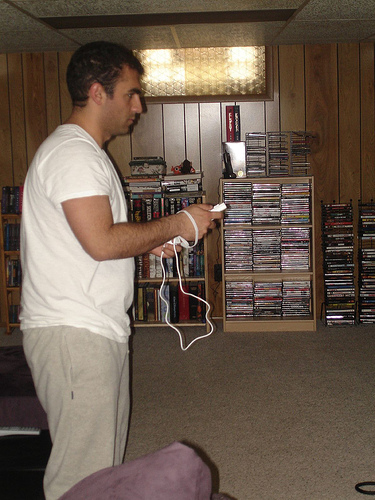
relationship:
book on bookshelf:
[133, 200, 142, 223] [131, 191, 219, 324]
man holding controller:
[18, 40, 228, 498] [165, 201, 227, 244]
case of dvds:
[219, 177, 326, 333] [319, 195, 373, 324]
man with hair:
[18, 40, 228, 498] [63, 35, 144, 109]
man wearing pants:
[18, 40, 228, 498] [28, 325, 141, 499]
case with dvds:
[214, 170, 325, 333] [249, 184, 283, 229]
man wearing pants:
[18, 40, 228, 498] [20, 325, 133, 500]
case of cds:
[219, 177, 326, 333] [223, 183, 308, 270]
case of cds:
[219, 177, 326, 333] [225, 281, 310, 317]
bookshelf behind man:
[125, 189, 213, 331] [18, 40, 228, 498]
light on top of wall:
[131, 44, 272, 100] [1, 39, 373, 320]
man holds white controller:
[18, 39, 227, 499] [182, 196, 232, 224]